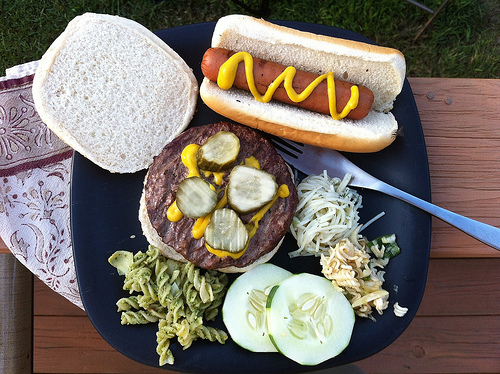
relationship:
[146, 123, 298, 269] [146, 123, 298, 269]
hamburger on top of hamburger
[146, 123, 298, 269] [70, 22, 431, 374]
hamburger on top of plate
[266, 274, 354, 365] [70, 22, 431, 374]
cucumber on top of plate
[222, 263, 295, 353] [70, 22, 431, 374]
cucumber on top of plate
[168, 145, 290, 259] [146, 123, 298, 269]
mustard on hamburger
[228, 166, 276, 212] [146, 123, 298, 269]
pickle on hamburger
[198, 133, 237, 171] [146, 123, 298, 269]
pickle on hamburger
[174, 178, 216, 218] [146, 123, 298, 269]
pickle on hamburger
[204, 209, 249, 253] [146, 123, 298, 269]
pickle on hamburger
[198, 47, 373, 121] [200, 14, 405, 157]
hotdog on bun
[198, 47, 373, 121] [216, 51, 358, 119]
hotdog has mustard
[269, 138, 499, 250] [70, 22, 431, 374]
fork on top of plate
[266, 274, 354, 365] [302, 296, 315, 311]
cucumber has seed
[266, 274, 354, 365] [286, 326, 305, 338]
cucumber has seed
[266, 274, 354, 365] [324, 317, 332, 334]
cucumber has seed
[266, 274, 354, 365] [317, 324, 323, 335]
cucumber has seed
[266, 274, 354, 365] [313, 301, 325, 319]
cucumber has seed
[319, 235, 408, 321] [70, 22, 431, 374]
food on plate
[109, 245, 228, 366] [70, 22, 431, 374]
pasta salad on plate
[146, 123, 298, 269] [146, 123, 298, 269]
hamburger on hamburger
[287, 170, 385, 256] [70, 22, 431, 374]
noodles on plate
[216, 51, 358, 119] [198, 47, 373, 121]
mustard on hotdog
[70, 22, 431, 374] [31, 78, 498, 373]
plate on table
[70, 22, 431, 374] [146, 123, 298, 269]
plate below hamburger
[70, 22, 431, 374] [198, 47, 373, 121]
plate below hotdog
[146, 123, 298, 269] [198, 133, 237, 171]
hamburger under pickle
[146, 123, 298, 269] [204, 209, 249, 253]
hamburger under pickle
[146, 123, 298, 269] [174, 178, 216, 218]
hamburger under pickle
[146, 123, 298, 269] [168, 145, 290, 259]
hamburger under mustard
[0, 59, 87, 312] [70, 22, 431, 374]
napkin below plate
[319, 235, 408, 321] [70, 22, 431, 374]
food on top of plate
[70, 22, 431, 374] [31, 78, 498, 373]
plate on top of table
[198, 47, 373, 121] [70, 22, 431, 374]
hotdog on top of plate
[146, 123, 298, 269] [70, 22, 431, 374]
hamburger on plate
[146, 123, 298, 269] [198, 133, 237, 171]
hamburger has pickle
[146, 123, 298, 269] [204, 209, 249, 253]
hamburger has pickle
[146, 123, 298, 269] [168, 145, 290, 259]
hamburger has mustard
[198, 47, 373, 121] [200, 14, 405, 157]
hotdog has bun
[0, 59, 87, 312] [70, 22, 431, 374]
napkin under plate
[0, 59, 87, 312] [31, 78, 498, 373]
napkin over table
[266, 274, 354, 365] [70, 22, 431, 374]
cucumber on plate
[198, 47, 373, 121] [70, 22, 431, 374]
hotdog on plate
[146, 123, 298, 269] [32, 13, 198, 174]
hamburger has top